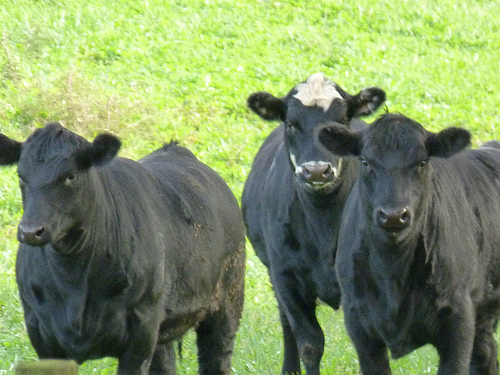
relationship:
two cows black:
[12, 96, 443, 365] [116, 165, 221, 286]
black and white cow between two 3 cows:
[289, 73, 350, 139] [0, 121, 247, 375]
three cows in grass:
[12, 96, 443, 365] [69, 11, 227, 70]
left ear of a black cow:
[1, 129, 25, 168] [236, 76, 381, 375]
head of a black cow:
[12, 126, 118, 265] [236, 76, 381, 375]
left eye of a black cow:
[15, 169, 31, 186] [236, 76, 381, 375]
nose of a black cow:
[13, 218, 49, 250] [236, 76, 381, 375]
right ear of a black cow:
[83, 127, 125, 166] [236, 76, 381, 375]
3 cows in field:
[0, 121, 247, 375] [1, 19, 500, 368]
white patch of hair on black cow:
[288, 71, 344, 111] [236, 76, 381, 375]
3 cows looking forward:
[0, 121, 247, 375] [207, 132, 255, 167]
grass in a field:
[69, 11, 227, 70] [1, 19, 500, 368]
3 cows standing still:
[0, 121, 247, 375] [24, 90, 486, 357]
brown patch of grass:
[42, 84, 108, 129] [69, 11, 227, 70]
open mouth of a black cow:
[302, 171, 333, 194] [236, 76, 381, 375]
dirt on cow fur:
[217, 241, 257, 329] [218, 266, 243, 313]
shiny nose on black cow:
[16, 224, 47, 246] [236, 76, 381, 375]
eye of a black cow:
[283, 120, 298, 134] [236, 76, 381, 375]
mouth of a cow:
[377, 226, 410, 236] [331, 104, 496, 369]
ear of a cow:
[436, 124, 476, 163] [331, 104, 496, 369]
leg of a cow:
[437, 280, 473, 372] [331, 104, 496, 369]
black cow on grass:
[331, 104, 496, 369] [69, 11, 227, 70]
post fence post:
[14, 354, 85, 375] [14, 352, 44, 369]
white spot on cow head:
[297, 79, 344, 106] [241, 69, 370, 189]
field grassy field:
[0, 0, 495, 375] [1, 19, 500, 368]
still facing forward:
[0, 75, 500, 375] [207, 132, 255, 167]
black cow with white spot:
[241, 76, 382, 299] [297, 79, 344, 106]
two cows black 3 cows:
[235, 75, 500, 375] [0, 121, 247, 375]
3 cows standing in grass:
[0, 121, 247, 375] [69, 11, 227, 70]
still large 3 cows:
[0, 75, 500, 375] [0, 121, 247, 375]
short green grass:
[418, 11, 469, 50] [69, 11, 227, 70]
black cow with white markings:
[236, 76, 381, 375] [283, 149, 345, 185]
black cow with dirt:
[236, 76, 381, 375] [217, 241, 257, 329]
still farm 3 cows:
[0, 75, 500, 375] [0, 121, 247, 375]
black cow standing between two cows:
[236, 76, 381, 375] [27, 226, 496, 289]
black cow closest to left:
[236, 76, 381, 375] [4, 175, 26, 308]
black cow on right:
[331, 104, 496, 369] [473, 187, 493, 326]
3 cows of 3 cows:
[0, 121, 247, 375] [22, 279, 491, 312]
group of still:
[8, 251, 498, 270] [0, 75, 500, 375]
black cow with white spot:
[236, 76, 381, 375] [297, 79, 344, 106]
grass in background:
[69, 11, 227, 70] [200, 16, 494, 56]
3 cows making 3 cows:
[0, 121, 247, 375] [0, 121, 247, 375]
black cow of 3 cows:
[236, 76, 381, 375] [0, 121, 247, 375]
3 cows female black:
[22, 279, 491, 312] [116, 165, 221, 286]